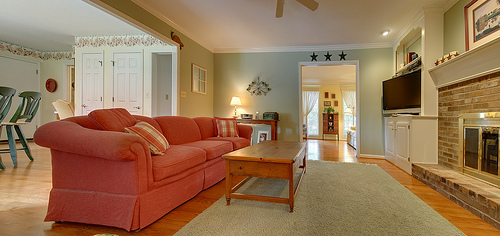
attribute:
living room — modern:
[0, 0, 500, 235]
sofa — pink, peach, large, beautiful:
[35, 107, 276, 230]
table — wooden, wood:
[224, 136, 309, 210]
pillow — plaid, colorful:
[125, 120, 167, 154]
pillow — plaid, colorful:
[214, 114, 240, 136]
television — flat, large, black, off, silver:
[382, 68, 425, 112]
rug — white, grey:
[170, 163, 461, 234]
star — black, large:
[338, 51, 348, 60]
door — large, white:
[298, 59, 359, 164]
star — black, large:
[324, 50, 333, 63]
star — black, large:
[309, 51, 320, 62]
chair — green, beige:
[3, 88, 42, 166]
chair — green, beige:
[0, 84, 20, 168]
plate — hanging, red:
[45, 78, 56, 94]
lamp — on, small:
[229, 94, 243, 118]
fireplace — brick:
[437, 74, 498, 192]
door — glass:
[457, 111, 498, 187]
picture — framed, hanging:
[464, 0, 500, 52]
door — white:
[112, 50, 144, 113]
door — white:
[81, 51, 107, 115]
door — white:
[0, 59, 39, 143]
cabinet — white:
[382, 115, 437, 175]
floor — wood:
[0, 141, 500, 234]